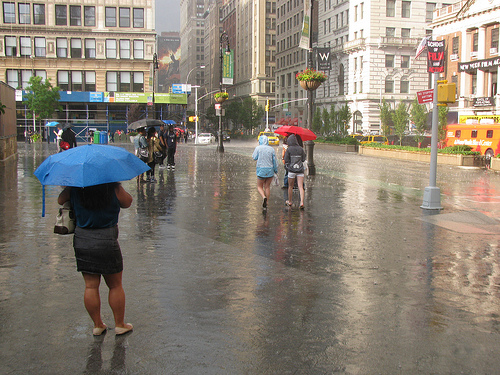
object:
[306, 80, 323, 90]
basket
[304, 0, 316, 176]
pole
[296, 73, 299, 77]
flower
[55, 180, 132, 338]
woman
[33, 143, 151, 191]
umbrella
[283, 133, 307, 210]
girl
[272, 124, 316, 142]
umbrella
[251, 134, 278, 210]
girl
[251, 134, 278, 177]
jacket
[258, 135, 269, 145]
hood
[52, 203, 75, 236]
handbag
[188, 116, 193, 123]
light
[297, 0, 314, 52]
banner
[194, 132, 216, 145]
car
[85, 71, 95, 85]
shade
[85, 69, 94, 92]
window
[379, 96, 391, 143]
tree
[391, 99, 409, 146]
tree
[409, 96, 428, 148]
tree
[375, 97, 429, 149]
line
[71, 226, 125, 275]
skirt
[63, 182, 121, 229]
shirt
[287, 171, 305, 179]
shorts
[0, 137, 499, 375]
sidewalk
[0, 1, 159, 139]
building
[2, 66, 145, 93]
row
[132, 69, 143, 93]
window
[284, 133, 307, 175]
sweatshirt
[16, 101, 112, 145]
scaffolding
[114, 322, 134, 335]
shoe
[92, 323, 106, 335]
shoe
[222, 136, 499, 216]
street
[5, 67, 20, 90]
window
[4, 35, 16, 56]
window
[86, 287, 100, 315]
skin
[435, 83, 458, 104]
light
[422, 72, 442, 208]
pole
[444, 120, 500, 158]
truck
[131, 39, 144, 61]
window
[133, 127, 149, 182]
man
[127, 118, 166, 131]
umbrella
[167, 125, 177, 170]
person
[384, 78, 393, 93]
window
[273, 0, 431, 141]
building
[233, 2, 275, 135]
building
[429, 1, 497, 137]
building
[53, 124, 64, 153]
person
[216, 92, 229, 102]
basket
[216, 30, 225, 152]
pole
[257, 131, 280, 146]
car